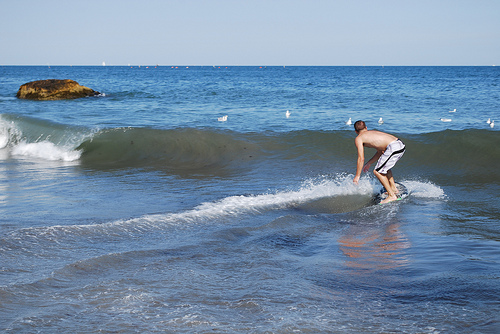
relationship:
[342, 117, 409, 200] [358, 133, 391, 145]
surfer showing off skin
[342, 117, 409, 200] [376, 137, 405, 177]
man wearing shorts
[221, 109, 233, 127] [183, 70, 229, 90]
seafull in ocean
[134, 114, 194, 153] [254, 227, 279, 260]
waves slamming against water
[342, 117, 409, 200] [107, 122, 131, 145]
surfer riding towards wave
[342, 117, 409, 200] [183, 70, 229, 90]
man surfing in ocean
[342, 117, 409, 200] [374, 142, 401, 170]
surfer wears trunks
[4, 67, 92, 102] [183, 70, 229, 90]
rock in ocean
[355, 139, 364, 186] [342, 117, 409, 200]
arm of surfer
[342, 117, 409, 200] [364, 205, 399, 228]
man standing on surfboard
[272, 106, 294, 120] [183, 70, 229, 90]
birds in ocean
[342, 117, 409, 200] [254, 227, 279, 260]
man surfing in water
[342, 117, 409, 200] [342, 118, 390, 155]
man leaning forward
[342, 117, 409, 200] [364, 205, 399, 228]
man leaning on surfboard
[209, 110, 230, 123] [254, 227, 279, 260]
bird sitting in water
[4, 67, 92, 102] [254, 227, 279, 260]
rock in water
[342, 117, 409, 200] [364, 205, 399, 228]
man on surfboard